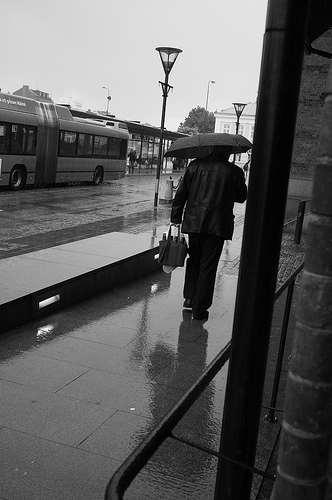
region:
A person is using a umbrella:
[166, 118, 251, 181]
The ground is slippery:
[59, 316, 160, 400]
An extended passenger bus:
[1, 65, 145, 213]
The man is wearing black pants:
[179, 225, 227, 304]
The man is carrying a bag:
[137, 137, 234, 313]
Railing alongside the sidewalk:
[103, 346, 212, 494]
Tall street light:
[149, 39, 186, 130]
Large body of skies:
[21, 9, 124, 58]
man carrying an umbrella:
[159, 131, 251, 318]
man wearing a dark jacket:
[169, 140, 248, 319]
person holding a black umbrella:
[158, 126, 254, 323]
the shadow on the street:
[131, 320, 223, 495]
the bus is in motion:
[1, 87, 136, 209]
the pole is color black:
[145, 39, 186, 213]